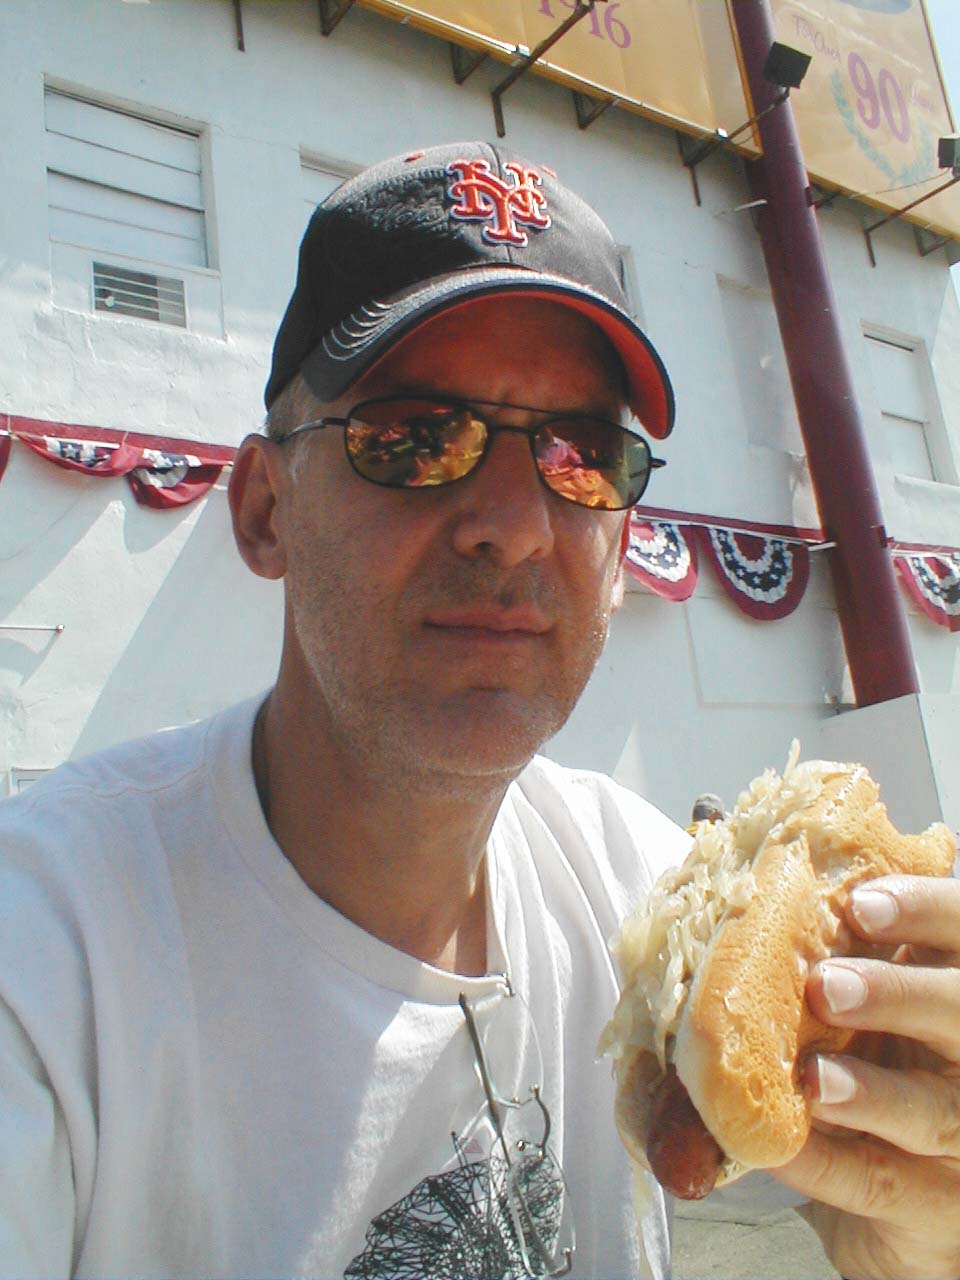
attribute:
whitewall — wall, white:
[2, 5, 949, 818]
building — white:
[6, 8, 956, 825]